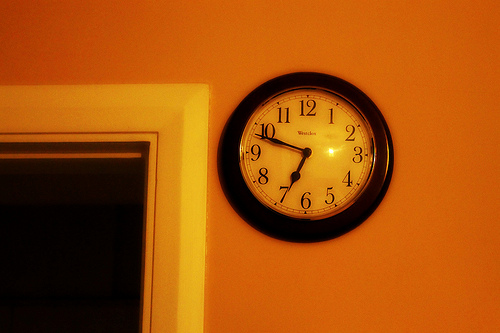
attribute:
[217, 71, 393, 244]
clock — black, white, analog, round, reflective, framed, wood, brown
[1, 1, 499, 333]
wall — orange, peach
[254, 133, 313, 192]
hands — black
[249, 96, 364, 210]
numbers — black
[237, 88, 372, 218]
frame — white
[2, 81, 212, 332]
door trim — white, wood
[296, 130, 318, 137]
name — black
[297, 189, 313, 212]
number 6 — black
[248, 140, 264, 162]
number 9 — black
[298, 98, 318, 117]
number 12 — black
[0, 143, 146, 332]
doorway — dark